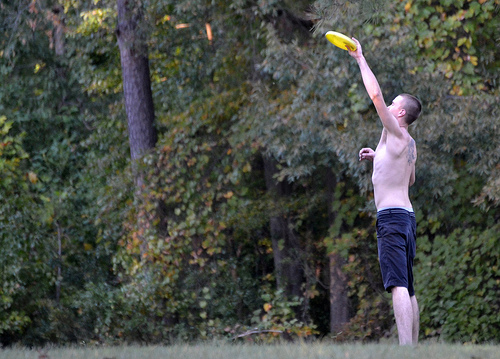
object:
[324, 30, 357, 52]
frisbee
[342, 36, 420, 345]
boy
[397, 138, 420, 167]
tattoo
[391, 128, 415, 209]
back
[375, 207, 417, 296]
shorts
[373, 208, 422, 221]
belt